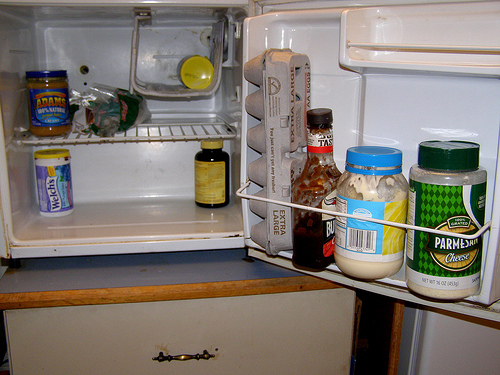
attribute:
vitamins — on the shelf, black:
[197, 138, 230, 209]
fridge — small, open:
[1, 2, 498, 304]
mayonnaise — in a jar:
[337, 147, 407, 280]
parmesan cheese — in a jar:
[407, 141, 487, 301]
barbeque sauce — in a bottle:
[291, 108, 336, 268]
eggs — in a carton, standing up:
[242, 50, 309, 258]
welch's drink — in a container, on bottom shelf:
[33, 149, 73, 216]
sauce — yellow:
[26, 70, 71, 136]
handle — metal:
[154, 348, 212, 363]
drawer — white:
[4, 288, 354, 375]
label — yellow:
[196, 159, 228, 205]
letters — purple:
[47, 173, 61, 212]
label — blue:
[29, 85, 67, 124]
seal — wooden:
[0, 277, 340, 310]